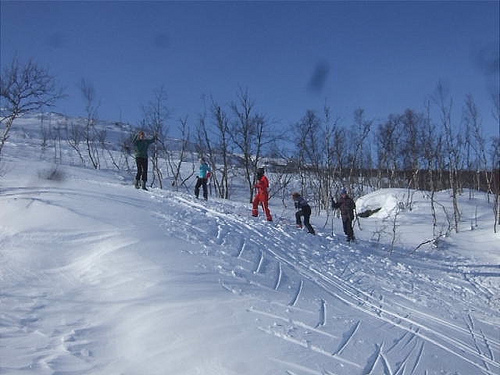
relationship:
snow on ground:
[35, 213, 245, 355] [0, 111, 484, 363]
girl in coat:
[188, 157, 212, 199] [195, 165, 210, 178]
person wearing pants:
[190, 148, 212, 195] [187, 178, 212, 205]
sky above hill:
[3, 2, 493, 176] [3, 133, 495, 373]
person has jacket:
[192, 156, 213, 198] [195, 168, 213, 176]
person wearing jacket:
[192, 156, 213, 198] [194, 160, 214, 180]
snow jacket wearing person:
[122, 132, 164, 160] [123, 127, 167, 196]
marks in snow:
[224, 240, 306, 310] [82, 140, 426, 359]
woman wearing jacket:
[116, 121, 163, 198] [137, 133, 155, 152]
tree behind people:
[325, 115, 350, 197] [126, 121, 389, 274]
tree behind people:
[285, 126, 317, 188] [126, 121, 389, 274]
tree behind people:
[362, 125, 421, 191] [126, 121, 389, 274]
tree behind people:
[236, 89, 255, 189] [126, 121, 389, 274]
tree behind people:
[432, 99, 469, 189] [126, 121, 389, 274]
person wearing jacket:
[190, 148, 212, 195] [192, 159, 211, 179]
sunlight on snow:
[41, 236, 173, 361] [1, 102, 499, 374]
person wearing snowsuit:
[328, 198, 358, 240] [332, 195, 362, 235]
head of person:
[140, 133, 143, 142] [130, 125, 160, 190]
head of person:
[197, 157, 204, 162] [192, 156, 213, 198]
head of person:
[255, 167, 261, 177] [243, 165, 277, 224]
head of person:
[291, 192, 301, 200] [291, 190, 314, 235]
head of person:
[342, 190, 348, 200] [328, 191, 358, 240]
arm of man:
[153, 132, 165, 148] [126, 125, 166, 188]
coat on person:
[193, 152, 225, 197] [190, 152, 215, 196]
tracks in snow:
[167, 184, 499, 369] [2, 155, 498, 372]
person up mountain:
[291, 190, 314, 235] [0, 107, 498, 374]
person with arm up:
[130, 125, 160, 190] [129, 130, 139, 147]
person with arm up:
[130, 125, 160, 190] [149, 127, 159, 144]